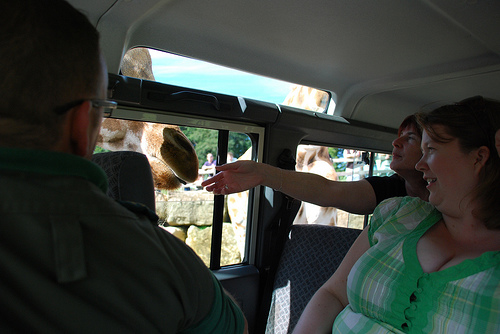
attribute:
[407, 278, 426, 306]
buttons — green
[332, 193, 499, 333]
shirt — green, white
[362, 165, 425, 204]
tee shirt — black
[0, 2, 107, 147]
hair — short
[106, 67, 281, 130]
handle — gray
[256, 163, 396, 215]
arm — outstretched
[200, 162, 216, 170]
shirt — purple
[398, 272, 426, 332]
buttons — green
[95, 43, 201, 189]
head — brown, white